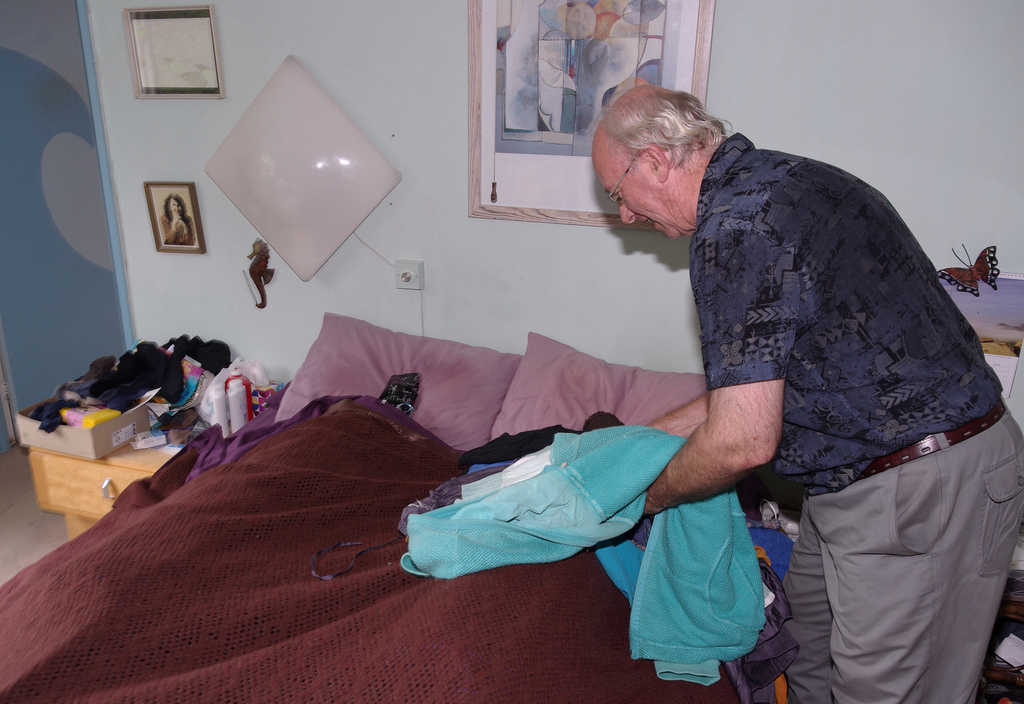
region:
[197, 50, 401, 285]
a wall mounted white ceiling light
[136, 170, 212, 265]
a framed portrait of a women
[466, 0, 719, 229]
a framed painting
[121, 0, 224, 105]
a framed document of some kind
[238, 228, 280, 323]
a small brown sea horse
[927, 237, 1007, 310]
a small fake butterfly with orange wings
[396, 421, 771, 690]
an aqua blue sweatshirt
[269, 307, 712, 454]
two light purple bedroom pillows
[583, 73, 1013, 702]
an old man in a blue shirt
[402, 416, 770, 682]
the jacket is blue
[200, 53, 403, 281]
the square light is white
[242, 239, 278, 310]
the seahorse is brown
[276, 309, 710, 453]
the pillows are purple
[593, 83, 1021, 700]
the old man is standing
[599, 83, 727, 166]
the hair is gray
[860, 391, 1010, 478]
the belt is brown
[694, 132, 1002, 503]
the shirt is blue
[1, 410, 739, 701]
the blanket is brown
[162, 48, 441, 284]
this is a square lamp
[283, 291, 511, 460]
this is a pillow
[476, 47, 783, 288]
the man is balding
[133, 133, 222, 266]
this is a photo in a frame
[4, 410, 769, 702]
there is a red blanket on the bed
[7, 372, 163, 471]
this is a shoe box with things in it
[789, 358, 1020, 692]
his pants are grey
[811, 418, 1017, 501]
this is a brown leather belt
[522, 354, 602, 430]
pillow on the bed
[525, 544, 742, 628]
sheet on the bed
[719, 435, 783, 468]
elbow on the man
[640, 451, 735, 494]
arm of the man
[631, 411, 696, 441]
arm of the man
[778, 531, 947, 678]
leg of the man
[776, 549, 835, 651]
leg o them an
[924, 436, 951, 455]
belt of the man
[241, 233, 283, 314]
seahorse on a wall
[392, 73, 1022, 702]
grey haired man is picking up clothes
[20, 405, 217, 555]
wooden nightstand with a drawer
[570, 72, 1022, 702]
man has silver grey hair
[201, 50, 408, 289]
diamond shaped wall lamp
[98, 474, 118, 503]
silver handle on a drawer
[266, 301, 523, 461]
purple pillow on a bed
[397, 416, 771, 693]
bright turquoise jacket on a bed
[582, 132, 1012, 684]
Man holding some clothes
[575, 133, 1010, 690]
Man in khaki pants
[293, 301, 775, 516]
Pillows on the bed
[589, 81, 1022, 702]
man is holding clothing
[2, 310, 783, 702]
bed is pink-colored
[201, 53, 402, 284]
light above bed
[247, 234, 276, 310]
seahorse on wall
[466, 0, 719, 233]
picture above bed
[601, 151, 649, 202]
glasses on man's head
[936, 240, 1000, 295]
butterfly decoration on wall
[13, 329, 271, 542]
nightstand is messy and cluttered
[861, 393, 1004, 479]
belt on man's waist is leather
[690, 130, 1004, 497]
shirt man is wearing is blue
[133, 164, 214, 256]
picture on the wall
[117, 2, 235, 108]
picture on the wall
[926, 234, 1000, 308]
butterfly on the dresser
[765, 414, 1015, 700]
man wearing gray pants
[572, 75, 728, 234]
man has gray hair